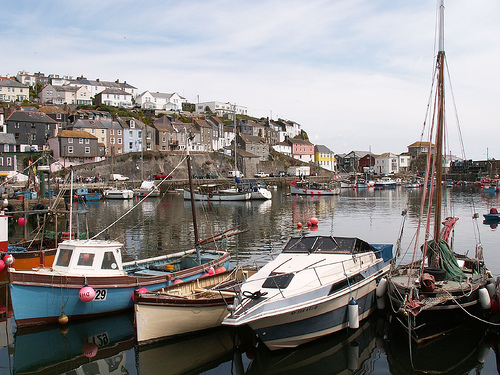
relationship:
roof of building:
[403, 140, 445, 152] [406, 137, 441, 168]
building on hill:
[61, 122, 94, 154] [1, 74, 344, 192]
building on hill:
[103, 106, 130, 155] [1, 74, 344, 192]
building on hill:
[122, 115, 142, 157] [1, 74, 344, 192]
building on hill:
[152, 118, 176, 148] [1, 74, 344, 192]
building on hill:
[192, 112, 212, 152] [1, 74, 344, 192]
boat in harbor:
[197, 227, 425, 352] [4, 159, 498, 373]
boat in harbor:
[110, 221, 268, 351] [4, 159, 498, 373]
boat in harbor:
[0, 210, 252, 326] [4, 159, 498, 373]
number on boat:
[97, 288, 109, 303] [0, 230, 226, 341]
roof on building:
[7, 95, 62, 137] [3, 108, 63, 146]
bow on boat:
[224, 269, 319, 332] [214, 234, 395, 353]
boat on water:
[183, 189, 251, 200] [198, 200, 275, 227]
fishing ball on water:
[291, 209, 338, 239] [204, 192, 408, 243]